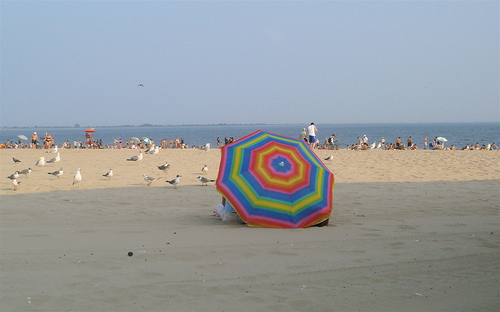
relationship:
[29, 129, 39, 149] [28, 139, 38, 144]
man in trunks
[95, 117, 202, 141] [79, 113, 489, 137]
island on water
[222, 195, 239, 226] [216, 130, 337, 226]
person under umbrella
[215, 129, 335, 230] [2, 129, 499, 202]
colored umbrellas on beach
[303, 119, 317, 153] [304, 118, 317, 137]
man in shirt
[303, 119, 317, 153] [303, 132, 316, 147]
man in trunks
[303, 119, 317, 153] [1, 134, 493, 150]
man on seashore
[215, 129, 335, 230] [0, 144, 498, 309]
colored umbrellas in sand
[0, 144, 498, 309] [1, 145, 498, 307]
sand on beach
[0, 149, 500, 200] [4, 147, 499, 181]
sun shining on sand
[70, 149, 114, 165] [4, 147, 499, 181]
sun shining on sand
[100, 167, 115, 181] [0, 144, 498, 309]
bird on sand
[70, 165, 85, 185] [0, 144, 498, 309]
bird on sand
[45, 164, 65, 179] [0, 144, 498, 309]
bird on sand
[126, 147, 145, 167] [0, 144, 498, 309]
bird on sand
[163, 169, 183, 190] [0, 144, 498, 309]
bird on sand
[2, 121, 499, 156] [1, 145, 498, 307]
people at beach